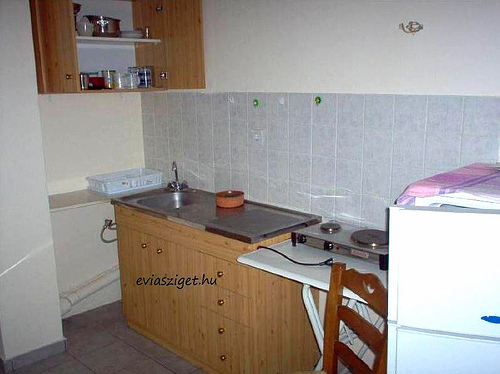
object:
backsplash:
[148, 88, 459, 209]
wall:
[204, 0, 397, 93]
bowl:
[215, 189, 245, 208]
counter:
[111, 184, 320, 247]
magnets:
[253, 99, 259, 107]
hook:
[398, 20, 423, 34]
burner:
[289, 218, 400, 272]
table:
[235, 221, 399, 303]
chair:
[310, 258, 384, 374]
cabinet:
[28, 1, 208, 94]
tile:
[57, 307, 148, 371]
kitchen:
[0, 0, 500, 374]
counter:
[235, 238, 385, 295]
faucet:
[164, 160, 188, 192]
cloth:
[396, 160, 500, 209]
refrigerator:
[387, 161, 500, 373]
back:
[329, 269, 412, 372]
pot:
[84, 14, 121, 37]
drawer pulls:
[142, 243, 163, 253]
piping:
[100, 218, 118, 243]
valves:
[101, 220, 117, 231]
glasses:
[142, 27, 150, 38]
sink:
[119, 184, 211, 215]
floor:
[67, 292, 147, 372]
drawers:
[198, 250, 248, 298]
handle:
[216, 270, 223, 278]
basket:
[83, 167, 162, 196]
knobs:
[217, 299, 224, 306]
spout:
[171, 161, 177, 172]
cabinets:
[109, 204, 323, 374]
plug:
[319, 257, 333, 267]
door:
[395, 211, 500, 338]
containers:
[77, 16, 94, 37]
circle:
[314, 96, 321, 106]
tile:
[364, 94, 397, 136]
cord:
[257, 245, 321, 266]